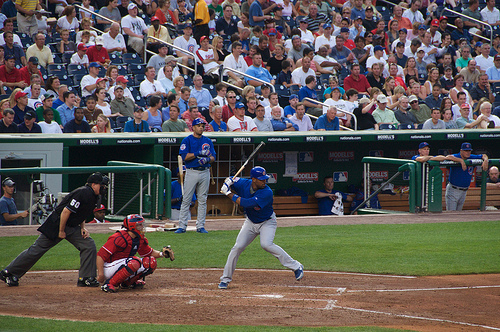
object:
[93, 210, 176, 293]
catcher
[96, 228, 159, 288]
uniform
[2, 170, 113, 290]
umpire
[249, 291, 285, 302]
home plate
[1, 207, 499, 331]
baseball field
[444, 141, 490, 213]
man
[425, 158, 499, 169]
rail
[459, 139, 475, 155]
hat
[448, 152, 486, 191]
shirt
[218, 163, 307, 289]
batter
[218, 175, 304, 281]
uniform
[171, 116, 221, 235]
man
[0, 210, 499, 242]
deck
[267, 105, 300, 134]
man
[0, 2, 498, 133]
stands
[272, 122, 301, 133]
folded arms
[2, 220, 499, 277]
grass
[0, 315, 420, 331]
grass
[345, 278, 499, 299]
line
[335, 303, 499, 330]
line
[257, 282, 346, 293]
line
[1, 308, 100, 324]
line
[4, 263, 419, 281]
line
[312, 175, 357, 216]
man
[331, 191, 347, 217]
towel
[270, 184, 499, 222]
bench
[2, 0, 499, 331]
scene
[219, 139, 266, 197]
bat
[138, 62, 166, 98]
spectator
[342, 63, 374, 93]
spectator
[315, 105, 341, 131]
spectator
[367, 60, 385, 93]
spectator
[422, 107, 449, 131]
spectator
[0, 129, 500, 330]
baseball game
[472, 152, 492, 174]
arm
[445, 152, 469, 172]
arm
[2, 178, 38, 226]
cameraman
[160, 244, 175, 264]
mitt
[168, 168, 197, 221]
player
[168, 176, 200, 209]
jersey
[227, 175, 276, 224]
jersey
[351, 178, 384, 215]
player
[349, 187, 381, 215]
jersey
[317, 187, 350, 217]
jersey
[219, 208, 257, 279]
pants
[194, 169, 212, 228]
pants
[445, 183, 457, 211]
pants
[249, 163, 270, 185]
helmet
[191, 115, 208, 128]
helmet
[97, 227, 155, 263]
jersey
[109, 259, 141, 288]
shin guard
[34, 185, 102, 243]
shirt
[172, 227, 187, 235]
spikes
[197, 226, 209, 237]
spikes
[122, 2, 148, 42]
fan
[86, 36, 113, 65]
fan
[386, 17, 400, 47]
fan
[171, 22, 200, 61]
fan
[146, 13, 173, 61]
fan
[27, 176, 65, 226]
camera